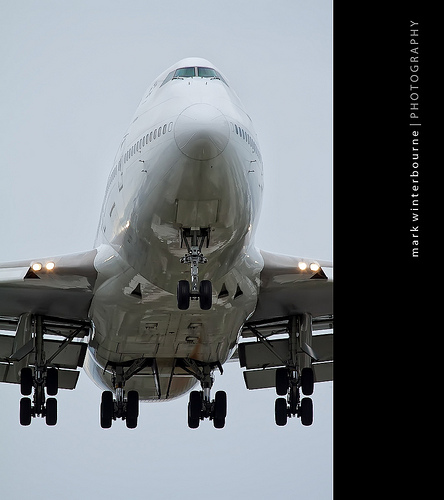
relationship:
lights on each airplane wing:
[16, 251, 72, 292] [7, 13, 409, 495]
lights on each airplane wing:
[292, 254, 325, 284] [7, 13, 409, 495]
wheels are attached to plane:
[172, 274, 219, 307] [20, 42, 334, 431]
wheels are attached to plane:
[264, 358, 316, 426] [20, 42, 334, 431]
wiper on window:
[172, 75, 186, 83] [160, 66, 198, 84]